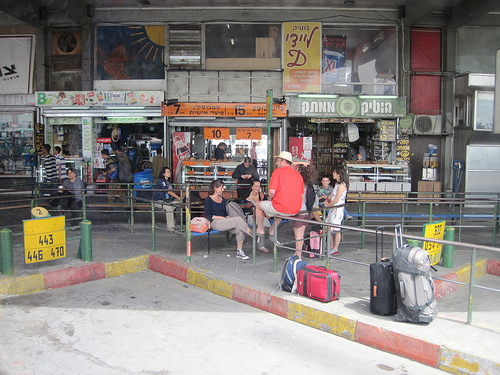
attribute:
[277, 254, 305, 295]
bag — blue, white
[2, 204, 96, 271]
sign — yellow, black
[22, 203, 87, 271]
sign — yellow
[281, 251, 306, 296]
back pack — blue, white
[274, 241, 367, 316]
suitcase — red, black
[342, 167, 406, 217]
ground — dark gray, light gray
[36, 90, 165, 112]
sign — white, long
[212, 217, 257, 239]
leg — crossed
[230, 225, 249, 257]
leg — crossed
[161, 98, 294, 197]
food stand — small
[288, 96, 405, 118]
sign — green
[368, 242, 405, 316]
suitcase — rolling, black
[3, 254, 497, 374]
curb — yellow, red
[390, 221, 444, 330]
suitcase — gray, rolling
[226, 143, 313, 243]
shirt — orange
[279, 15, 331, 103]
sign. — long, orange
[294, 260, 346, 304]
luggage — red, black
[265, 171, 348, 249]
t shirt — red